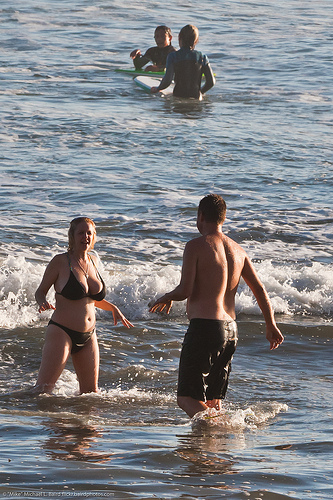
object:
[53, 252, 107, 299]
bikini top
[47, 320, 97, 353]
bikini bottom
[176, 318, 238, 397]
swim trunks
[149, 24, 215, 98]
boy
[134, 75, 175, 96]
surfboard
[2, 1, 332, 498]
water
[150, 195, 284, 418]
man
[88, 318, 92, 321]
belly button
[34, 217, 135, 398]
woman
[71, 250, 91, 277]
necklace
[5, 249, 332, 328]
wave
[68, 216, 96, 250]
hair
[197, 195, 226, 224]
hair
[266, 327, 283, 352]
hand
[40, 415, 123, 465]
reflection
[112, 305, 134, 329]
hand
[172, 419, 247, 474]
reflection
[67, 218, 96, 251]
head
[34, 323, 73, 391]
leg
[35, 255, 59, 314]
arm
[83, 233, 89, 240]
nose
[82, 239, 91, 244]
mouth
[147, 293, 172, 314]
hand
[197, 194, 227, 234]
head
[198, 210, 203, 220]
ear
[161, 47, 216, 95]
wet suit